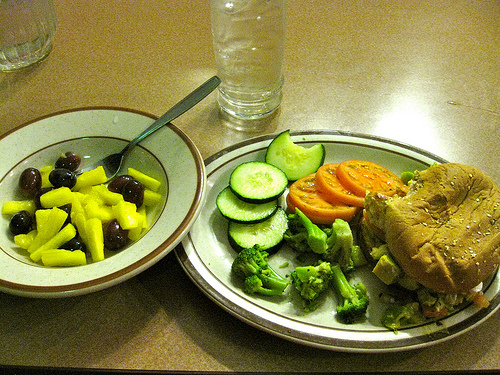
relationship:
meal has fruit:
[48, 147, 88, 172] [3, 209, 32, 240]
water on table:
[201, 2, 293, 127] [298, 0, 499, 141]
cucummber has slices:
[264, 131, 331, 181] [215, 157, 290, 258]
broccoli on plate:
[229, 246, 290, 301] [171, 122, 498, 358]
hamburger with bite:
[358, 162, 500, 336] [374, 172, 429, 196]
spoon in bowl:
[74, 70, 222, 196] [0, 101, 211, 301]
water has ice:
[201, 2, 293, 127] [251, 11, 278, 35]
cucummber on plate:
[264, 131, 331, 181] [171, 122, 498, 358]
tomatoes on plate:
[277, 159, 419, 223] [171, 122, 498, 358]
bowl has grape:
[0, 101, 211, 301] [50, 164, 74, 187]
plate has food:
[171, 122, 498, 358] [358, 162, 500, 336]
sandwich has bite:
[358, 162, 500, 336] [374, 172, 429, 196]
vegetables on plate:
[230, 205, 374, 323] [171, 122, 498, 358]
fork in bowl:
[74, 70, 222, 196] [0, 101, 211, 301]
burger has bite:
[358, 162, 500, 336] [374, 172, 429, 196]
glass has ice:
[201, 2, 293, 127] [251, 11, 278, 35]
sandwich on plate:
[358, 162, 500, 336] [171, 122, 498, 358]